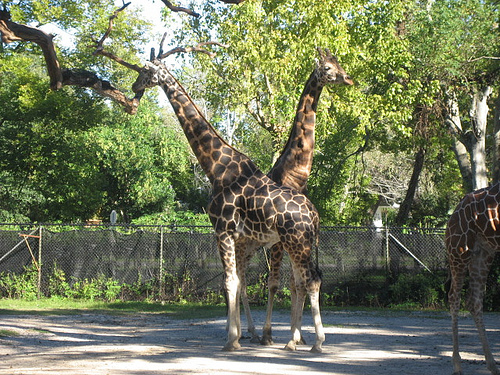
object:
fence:
[0, 223, 499, 310]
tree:
[347, 10, 491, 107]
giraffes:
[130, 46, 326, 354]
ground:
[0, 299, 499, 373]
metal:
[108, 228, 185, 286]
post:
[37, 223, 45, 296]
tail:
[301, 219, 325, 280]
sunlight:
[116, 0, 186, 66]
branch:
[49, 66, 136, 98]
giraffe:
[443, 185, 498, 373]